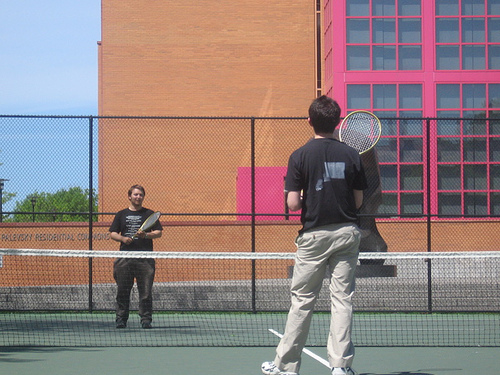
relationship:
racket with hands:
[133, 204, 161, 248] [119, 225, 148, 237]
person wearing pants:
[262, 94, 366, 373] [275, 219, 362, 369]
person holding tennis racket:
[262, 94, 366, 373] [338, 109, 380, 152]